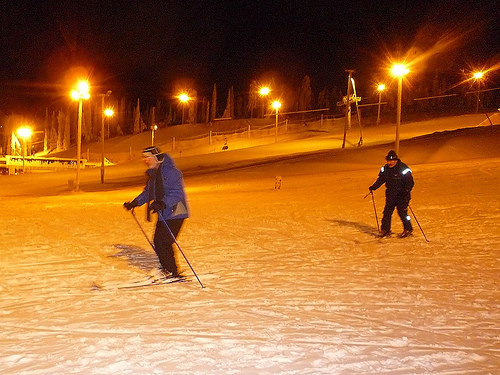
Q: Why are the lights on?
A: It is nighttime.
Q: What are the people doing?
A: The people are skiing.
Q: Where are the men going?
A: Down a slope.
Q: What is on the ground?
A: Snow is on the ground.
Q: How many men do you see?
A: 2 men.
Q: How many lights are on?
A: 8 lights are on.